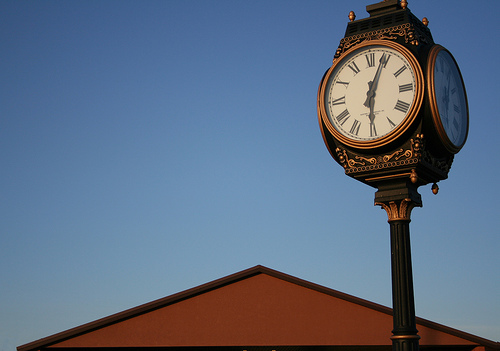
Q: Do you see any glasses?
A: No, there are no glasses.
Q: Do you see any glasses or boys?
A: No, there are no glasses or boys.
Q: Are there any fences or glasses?
A: No, there are no glasses or fences.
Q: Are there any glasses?
A: No, there are no glasses.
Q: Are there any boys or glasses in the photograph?
A: No, there are no glasses or boys.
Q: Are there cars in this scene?
A: No, there are no cars.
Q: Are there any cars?
A: No, there are no cars.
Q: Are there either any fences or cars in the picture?
A: No, there are no cars or fences.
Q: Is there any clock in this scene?
A: Yes, there is a clock.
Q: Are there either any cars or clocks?
A: Yes, there is a clock.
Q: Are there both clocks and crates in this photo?
A: No, there is a clock but no crates.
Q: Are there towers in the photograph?
A: No, there are no towers.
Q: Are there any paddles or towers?
A: No, there are no towers or paddles.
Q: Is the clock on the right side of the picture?
A: Yes, the clock is on the right of the image.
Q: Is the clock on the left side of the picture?
A: No, the clock is on the right of the image.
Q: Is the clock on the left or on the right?
A: The clock is on the right of the image.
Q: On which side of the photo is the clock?
A: The clock is on the right of the image.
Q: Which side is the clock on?
A: The clock is on the right of the image.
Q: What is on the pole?
A: The clock is on the pole.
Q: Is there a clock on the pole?
A: Yes, there is a clock on the pole.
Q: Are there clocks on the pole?
A: Yes, there is a clock on the pole.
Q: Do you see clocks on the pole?
A: Yes, there is a clock on the pole.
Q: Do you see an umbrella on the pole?
A: No, there is a clock on the pole.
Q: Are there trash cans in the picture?
A: No, there are no trash cans.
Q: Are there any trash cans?
A: No, there are no trash cans.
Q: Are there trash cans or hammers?
A: No, there are no trash cans or hammers.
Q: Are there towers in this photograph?
A: No, there are no towers.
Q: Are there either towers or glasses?
A: No, there are no towers or glasses.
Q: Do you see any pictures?
A: No, there are no pictures.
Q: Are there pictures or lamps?
A: No, there are no pictures or lamps.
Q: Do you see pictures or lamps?
A: No, there are no pictures or lamps.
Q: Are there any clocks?
A: Yes, there is a clock.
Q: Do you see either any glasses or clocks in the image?
A: Yes, there is a clock.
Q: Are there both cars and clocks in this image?
A: No, there is a clock but no cars.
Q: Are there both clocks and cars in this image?
A: No, there is a clock but no cars.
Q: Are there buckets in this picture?
A: No, there are no buckets.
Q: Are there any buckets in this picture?
A: No, there are no buckets.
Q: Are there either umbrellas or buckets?
A: No, there are no buckets or umbrellas.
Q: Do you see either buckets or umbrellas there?
A: No, there are no buckets or umbrellas.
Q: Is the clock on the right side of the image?
A: Yes, the clock is on the right of the image.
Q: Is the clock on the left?
A: No, the clock is on the right of the image.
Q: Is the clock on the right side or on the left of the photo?
A: The clock is on the right of the image.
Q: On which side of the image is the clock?
A: The clock is on the right of the image.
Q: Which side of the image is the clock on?
A: The clock is on the right of the image.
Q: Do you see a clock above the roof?
A: Yes, there is a clock above the roof.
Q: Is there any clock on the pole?
A: Yes, there is a clock on the pole.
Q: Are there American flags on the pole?
A: No, there is a clock on the pole.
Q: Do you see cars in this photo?
A: No, there are no cars.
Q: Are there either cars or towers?
A: No, there are no cars or towers.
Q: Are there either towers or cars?
A: No, there are no cars or towers.